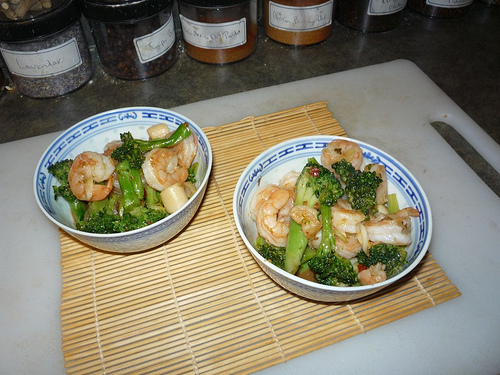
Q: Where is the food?
A: In bowls.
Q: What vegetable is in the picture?
A: Broccoli.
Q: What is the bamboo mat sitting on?
A: A cutting board.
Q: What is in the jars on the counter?
A: Spices.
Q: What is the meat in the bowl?
A: Shrimp.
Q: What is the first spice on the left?
A: Lavender.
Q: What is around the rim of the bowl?
A: A blue design.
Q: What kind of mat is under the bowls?
A: Bamboo.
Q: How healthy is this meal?
A: Very healthy.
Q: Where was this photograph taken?
A: In a kitchen.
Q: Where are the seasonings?
A: Behind the bowls.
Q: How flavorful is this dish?
A: Quite flavorful.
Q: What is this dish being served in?
A: Bowls.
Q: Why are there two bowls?
A: Dinner for two.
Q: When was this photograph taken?
A: Early evening.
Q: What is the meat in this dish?
A: Shrimp.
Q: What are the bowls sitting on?
A: A bamboo mat.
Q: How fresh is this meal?
A: Very fresh.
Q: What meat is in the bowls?
A: Shrimp.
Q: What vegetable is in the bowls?
A: Broccoli.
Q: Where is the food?
A: In the bowls.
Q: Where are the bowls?
A: On the bamboo mat.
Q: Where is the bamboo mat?
A: On the cutting board.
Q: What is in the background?
A: Herbs and spices.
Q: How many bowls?
A: Two.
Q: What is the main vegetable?
A: Broccoli.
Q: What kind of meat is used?
A: Shrimp.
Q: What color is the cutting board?
A: White.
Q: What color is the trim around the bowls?
A: Blue.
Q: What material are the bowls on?
A: Bamboo.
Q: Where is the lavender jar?
A: Back, left.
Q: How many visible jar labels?
A: 6.